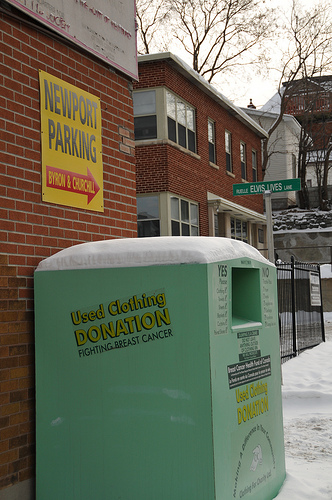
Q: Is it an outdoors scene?
A: Yes, it is outdoors.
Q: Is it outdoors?
A: Yes, it is outdoors.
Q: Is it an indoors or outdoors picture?
A: It is outdoors.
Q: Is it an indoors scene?
A: No, it is outdoors.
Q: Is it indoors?
A: No, it is outdoors.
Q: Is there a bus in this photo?
A: No, there are no buses.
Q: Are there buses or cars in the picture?
A: No, there are no buses or cars.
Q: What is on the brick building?
A: The sign is on the building.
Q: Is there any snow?
A: Yes, there is snow.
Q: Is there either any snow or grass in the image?
A: Yes, there is snow.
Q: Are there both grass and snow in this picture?
A: No, there is snow but no grass.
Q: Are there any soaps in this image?
A: No, there are no soaps.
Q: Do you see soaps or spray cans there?
A: No, there are no soaps or spray cans.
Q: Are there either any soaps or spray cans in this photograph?
A: No, there are no soaps or spray cans.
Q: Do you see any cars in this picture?
A: No, there are no cars.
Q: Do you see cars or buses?
A: No, there are no cars or buses.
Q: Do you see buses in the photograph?
A: No, there are no buses.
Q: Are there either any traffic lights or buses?
A: No, there are no buses or traffic lights.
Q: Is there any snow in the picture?
A: Yes, there is snow.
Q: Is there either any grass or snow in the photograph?
A: Yes, there is snow.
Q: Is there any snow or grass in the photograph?
A: Yes, there is snow.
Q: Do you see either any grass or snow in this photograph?
A: Yes, there is snow.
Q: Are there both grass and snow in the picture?
A: No, there is snow but no grass.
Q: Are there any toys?
A: No, there are no toys.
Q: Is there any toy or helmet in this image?
A: No, there are no toys or helmets.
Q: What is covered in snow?
A: The ground is covered in snow.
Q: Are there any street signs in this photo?
A: Yes, there is a street sign.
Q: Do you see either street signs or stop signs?
A: Yes, there is a street sign.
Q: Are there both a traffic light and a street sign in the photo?
A: No, there is a street sign but no traffic lights.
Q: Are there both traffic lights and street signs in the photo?
A: No, there is a street sign but no traffic lights.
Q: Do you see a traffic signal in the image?
A: No, there are no traffic lights.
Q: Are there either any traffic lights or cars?
A: No, there are no traffic lights or cars.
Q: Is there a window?
A: Yes, there are windows.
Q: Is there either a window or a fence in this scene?
A: Yes, there are windows.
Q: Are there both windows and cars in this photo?
A: No, there are windows but no cars.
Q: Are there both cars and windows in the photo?
A: No, there are windows but no cars.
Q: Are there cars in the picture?
A: No, there are no cars.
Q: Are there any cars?
A: No, there are no cars.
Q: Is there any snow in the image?
A: Yes, there is snow.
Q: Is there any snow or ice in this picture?
A: Yes, there is snow.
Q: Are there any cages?
A: No, there are no cages.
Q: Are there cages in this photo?
A: No, there are no cages.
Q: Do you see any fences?
A: Yes, there is a fence.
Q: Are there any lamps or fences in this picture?
A: Yes, there is a fence.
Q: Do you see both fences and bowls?
A: No, there is a fence but no bowls.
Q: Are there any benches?
A: No, there are no benches.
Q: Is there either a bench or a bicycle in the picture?
A: No, there are no benches or bicycles.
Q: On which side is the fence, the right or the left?
A: The fence is on the right of the image.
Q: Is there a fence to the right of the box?
A: Yes, there is a fence to the right of the box.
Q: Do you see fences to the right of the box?
A: Yes, there is a fence to the right of the box.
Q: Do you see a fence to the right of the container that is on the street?
A: Yes, there is a fence to the right of the box.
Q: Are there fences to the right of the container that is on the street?
A: Yes, there is a fence to the right of the box.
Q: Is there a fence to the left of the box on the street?
A: No, the fence is to the right of the box.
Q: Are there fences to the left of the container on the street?
A: No, the fence is to the right of the box.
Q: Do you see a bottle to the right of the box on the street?
A: No, there is a fence to the right of the box.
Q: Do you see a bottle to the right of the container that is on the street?
A: No, there is a fence to the right of the box.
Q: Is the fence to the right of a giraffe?
A: No, the fence is to the right of the box.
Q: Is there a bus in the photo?
A: No, there are no buses.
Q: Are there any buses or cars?
A: No, there are no buses or cars.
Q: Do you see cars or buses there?
A: No, there are no buses or cars.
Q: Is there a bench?
A: No, there are no benches.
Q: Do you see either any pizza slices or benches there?
A: No, there are no benches or pizza slices.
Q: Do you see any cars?
A: No, there are no cars.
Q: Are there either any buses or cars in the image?
A: No, there are no cars or buses.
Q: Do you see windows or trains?
A: Yes, there is a window.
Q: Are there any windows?
A: Yes, there is a window.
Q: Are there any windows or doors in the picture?
A: Yes, there is a window.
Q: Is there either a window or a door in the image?
A: Yes, there is a window.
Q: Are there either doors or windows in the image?
A: Yes, there is a window.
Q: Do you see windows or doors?
A: Yes, there is a window.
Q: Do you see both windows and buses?
A: No, there is a window but no buses.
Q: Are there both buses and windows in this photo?
A: No, there is a window but no buses.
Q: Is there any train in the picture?
A: No, there are no trains.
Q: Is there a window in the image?
A: Yes, there is a window.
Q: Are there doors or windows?
A: Yes, there is a window.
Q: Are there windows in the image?
A: Yes, there is a window.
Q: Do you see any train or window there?
A: Yes, there is a window.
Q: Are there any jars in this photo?
A: No, there are no jars.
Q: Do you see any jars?
A: No, there are no jars.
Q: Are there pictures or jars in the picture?
A: No, there are no jars or pictures.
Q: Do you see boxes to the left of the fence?
A: Yes, there is a box to the left of the fence.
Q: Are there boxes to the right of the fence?
A: No, the box is to the left of the fence.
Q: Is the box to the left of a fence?
A: Yes, the box is to the left of a fence.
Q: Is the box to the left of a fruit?
A: No, the box is to the left of a fence.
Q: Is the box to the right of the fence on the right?
A: No, the box is to the left of the fence.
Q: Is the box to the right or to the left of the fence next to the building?
A: The box is to the left of the fence.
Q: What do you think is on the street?
A: The box is on the street.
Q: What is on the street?
A: The box is on the street.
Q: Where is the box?
A: The box is on the street.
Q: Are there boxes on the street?
A: Yes, there is a box on the street.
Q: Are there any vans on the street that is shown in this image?
A: No, there is a box on the street.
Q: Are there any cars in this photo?
A: No, there are no cars.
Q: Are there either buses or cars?
A: No, there are no cars or buses.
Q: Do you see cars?
A: No, there are no cars.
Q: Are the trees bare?
A: Yes, the trees are bare.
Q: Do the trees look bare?
A: Yes, the trees are bare.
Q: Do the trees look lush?
A: No, the trees are bare.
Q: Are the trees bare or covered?
A: The trees are bare.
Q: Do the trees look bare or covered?
A: The trees are bare.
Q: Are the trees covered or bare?
A: The trees are bare.